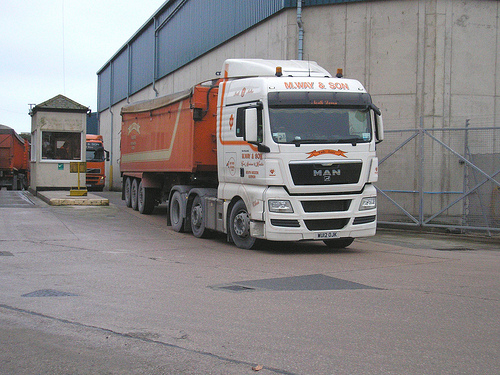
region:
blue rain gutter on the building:
[294, 1, 305, 58]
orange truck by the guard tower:
[83, 132, 113, 190]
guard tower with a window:
[26, 93, 88, 193]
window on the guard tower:
[38, 127, 83, 162]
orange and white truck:
[117, 55, 386, 251]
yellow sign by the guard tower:
[66, 157, 89, 197]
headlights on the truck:
[267, 196, 376, 215]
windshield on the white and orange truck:
[266, 101, 374, 145]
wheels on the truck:
[121, 173, 258, 250]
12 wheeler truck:
[116, 36, 379, 251]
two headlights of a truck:
[263, 190, 379, 242]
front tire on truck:
[225, 192, 261, 248]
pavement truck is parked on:
[6, 91, 422, 353]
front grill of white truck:
[285, 151, 379, 202]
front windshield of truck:
[265, 91, 374, 145]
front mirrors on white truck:
[216, 103, 405, 151]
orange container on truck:
[120, 66, 218, 179]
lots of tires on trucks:
[116, 162, 275, 282]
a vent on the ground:
[221, 277, 249, 294]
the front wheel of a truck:
[229, 205, 260, 245]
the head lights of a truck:
[263, 195, 379, 220]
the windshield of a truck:
[267, 106, 374, 146]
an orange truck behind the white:
[79, 131, 111, 191]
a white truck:
[121, 75, 378, 243]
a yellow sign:
[68, 160, 90, 194]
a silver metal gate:
[377, 127, 499, 234]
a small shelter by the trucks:
[29, 95, 95, 185]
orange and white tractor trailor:
[118, 57, 378, 253]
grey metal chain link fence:
[381, 121, 499, 234]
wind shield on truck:
[270, 105, 372, 144]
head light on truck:
[268, 197, 293, 214]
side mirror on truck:
[244, 104, 270, 154]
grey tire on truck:
[228, 201, 254, 251]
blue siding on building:
[98, 1, 297, 114]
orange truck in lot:
[84, 134, 111, 187]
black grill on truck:
[301, 199, 353, 230]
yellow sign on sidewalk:
[68, 162, 87, 198]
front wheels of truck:
[221, 197, 261, 254]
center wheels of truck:
[159, 183, 216, 241]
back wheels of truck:
[114, 171, 151, 214]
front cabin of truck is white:
[211, 58, 386, 248]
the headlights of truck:
[262, 193, 377, 215]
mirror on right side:
[368, 103, 390, 153]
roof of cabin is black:
[23, 90, 97, 197]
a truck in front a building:
[96, 2, 441, 257]